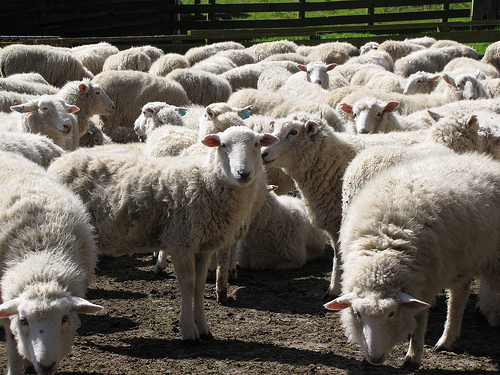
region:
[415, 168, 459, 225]
part of a sheep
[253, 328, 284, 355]
part of a shade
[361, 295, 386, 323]
head of a sheep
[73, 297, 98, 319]
edge of an ear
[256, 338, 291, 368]
part of a shade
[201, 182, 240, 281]
chest of a sheep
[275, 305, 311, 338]
part of a ground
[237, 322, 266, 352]
edge o a shade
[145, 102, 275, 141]
two sheep with blue ear tags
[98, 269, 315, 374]
muddy ground beneath sheep hooves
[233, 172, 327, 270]
a laying down sheep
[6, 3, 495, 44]
wooden slatted fence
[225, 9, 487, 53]
green grass growing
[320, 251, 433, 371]
fluffy faced sheep with its head down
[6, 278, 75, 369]
sheep with black dot on it's face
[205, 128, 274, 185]
sheep looking directly at camera man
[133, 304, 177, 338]
small spot of green grass in mud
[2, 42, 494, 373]
herd of sheep in a pen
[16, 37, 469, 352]
a group of sheep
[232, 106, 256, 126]
a small blue ear tag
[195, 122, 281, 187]
a white furry face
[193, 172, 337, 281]
a sheep laying down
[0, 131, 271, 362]
a couple sheep standing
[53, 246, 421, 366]
a few patches of grass in dirt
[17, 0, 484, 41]
a long wooden fence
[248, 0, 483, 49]
some grass in the background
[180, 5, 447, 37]
a few fence rails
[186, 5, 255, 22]
a shadow in the grass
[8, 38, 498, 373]
A heard of sheep.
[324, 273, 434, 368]
Sheeps head near the ground.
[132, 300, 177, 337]
Grass starting to sprout.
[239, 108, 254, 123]
A blue ear tag.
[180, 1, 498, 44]
A wodden fence.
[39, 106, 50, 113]
The eye of the sheep.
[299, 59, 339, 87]
The head of a sheep.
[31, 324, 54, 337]
Dirt on the face..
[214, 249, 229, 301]
A dirty sheep leg.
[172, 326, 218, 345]
Two front sheep hooves.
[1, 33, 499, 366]
a flock of sheep in their pen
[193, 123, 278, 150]
ears of sheep are on the side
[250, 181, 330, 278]
a sheep is lying in the ground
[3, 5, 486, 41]
a wooden fence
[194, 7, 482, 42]
green grass behind a fence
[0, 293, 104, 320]
two ears on side of head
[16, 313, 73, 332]
eyes of sheep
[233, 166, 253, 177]
nostrils of sheep are black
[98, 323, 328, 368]
shadow cast on the ground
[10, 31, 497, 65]
bodies of sheeps can be seen